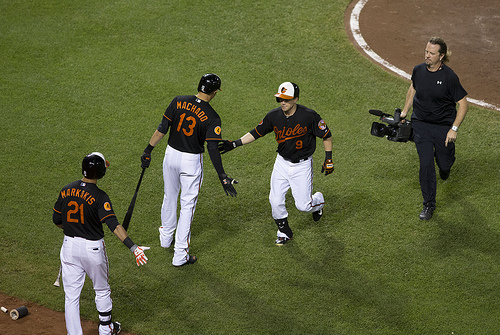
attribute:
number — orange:
[174, 111, 198, 141]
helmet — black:
[195, 70, 223, 95]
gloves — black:
[204, 135, 241, 197]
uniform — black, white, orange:
[156, 95, 224, 267]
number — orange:
[293, 138, 303, 150]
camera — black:
[368, 104, 413, 142]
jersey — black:
[159, 92, 229, 154]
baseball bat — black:
[123, 164, 146, 233]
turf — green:
[78, 51, 163, 97]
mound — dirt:
[384, 13, 494, 68]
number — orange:
[286, 140, 318, 162]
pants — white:
[154, 143, 230, 277]